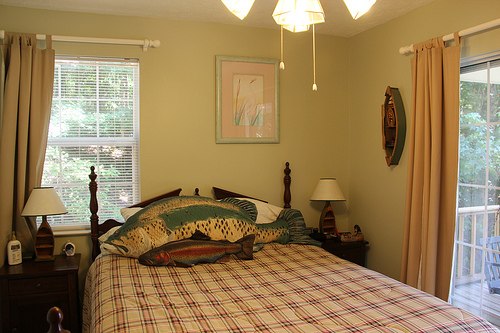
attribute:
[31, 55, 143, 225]
shades — white, open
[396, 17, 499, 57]
curtainrod — white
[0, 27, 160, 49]
curtainrod — white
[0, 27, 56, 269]
curtains — tan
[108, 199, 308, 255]
pillow — big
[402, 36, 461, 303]
curtains — tan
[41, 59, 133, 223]
mini blinds — white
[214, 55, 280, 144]
picture — framed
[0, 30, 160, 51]
rod — white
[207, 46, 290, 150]
picture — framed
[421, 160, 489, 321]
balcony — wooden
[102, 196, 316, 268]
pillows — fish-shaped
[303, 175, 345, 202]
shade — white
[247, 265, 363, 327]
spread — plaid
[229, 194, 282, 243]
pillow — fish-shaped